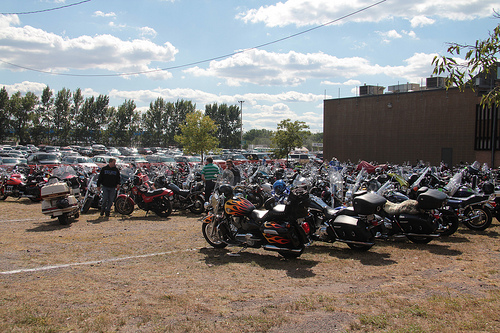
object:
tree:
[107, 90, 140, 147]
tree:
[142, 95, 173, 148]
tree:
[106, 96, 138, 144]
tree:
[49, 83, 72, 145]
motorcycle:
[115, 167, 175, 220]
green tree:
[170, 110, 224, 164]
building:
[306, 82, 498, 174]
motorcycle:
[201, 187, 311, 259]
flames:
[220, 193, 258, 218]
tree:
[177, 112, 220, 161]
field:
[1, 190, 495, 331]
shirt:
[200, 165, 221, 182]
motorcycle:
[352, 177, 451, 248]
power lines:
[0, 1, 91, 16]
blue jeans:
[100, 185, 118, 217]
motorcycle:
[37, 172, 83, 229]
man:
[198, 152, 225, 202]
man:
[87, 151, 127, 221]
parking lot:
[0, 131, 500, 265]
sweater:
[89, 158, 124, 218]